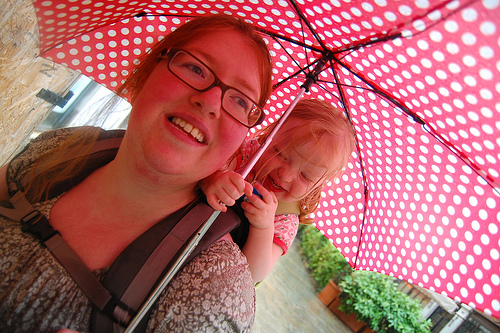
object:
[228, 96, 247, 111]
eyes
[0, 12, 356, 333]
people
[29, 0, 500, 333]
umbrella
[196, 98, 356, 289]
little girl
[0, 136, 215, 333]
straps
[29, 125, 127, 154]
shoulders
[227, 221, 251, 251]
back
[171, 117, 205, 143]
teeth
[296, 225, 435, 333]
bushes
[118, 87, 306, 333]
pole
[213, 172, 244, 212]
handle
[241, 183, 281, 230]
hands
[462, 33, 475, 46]
polka dots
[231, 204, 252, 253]
back pack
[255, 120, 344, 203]
face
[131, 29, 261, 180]
face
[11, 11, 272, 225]
hair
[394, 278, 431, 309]
gate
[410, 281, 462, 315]
hinge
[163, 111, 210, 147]
mouth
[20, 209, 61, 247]
harness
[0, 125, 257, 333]
blouse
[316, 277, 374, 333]
hedge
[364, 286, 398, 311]
leaves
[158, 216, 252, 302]
shoulder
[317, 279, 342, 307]
planter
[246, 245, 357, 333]
ground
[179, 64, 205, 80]
eyes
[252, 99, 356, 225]
hair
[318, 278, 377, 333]
pots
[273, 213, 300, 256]
shirt